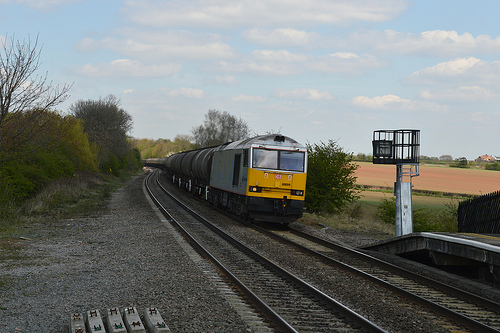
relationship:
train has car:
[165, 134, 307, 222] [210, 135, 307, 213]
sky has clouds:
[0, 1, 498, 161] [91, 0, 487, 111]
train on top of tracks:
[165, 134, 307, 222] [136, 156, 499, 332]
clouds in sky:
[91, 0, 487, 111] [0, 1, 498, 161]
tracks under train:
[136, 156, 499, 332] [165, 134, 307, 222]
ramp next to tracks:
[359, 227, 499, 277] [136, 156, 499, 332]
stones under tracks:
[4, 167, 256, 328] [136, 156, 499, 332]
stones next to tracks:
[4, 167, 256, 328] [136, 156, 499, 332]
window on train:
[251, 147, 277, 169] [165, 134, 307, 222]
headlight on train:
[249, 183, 261, 191] [165, 134, 307, 222]